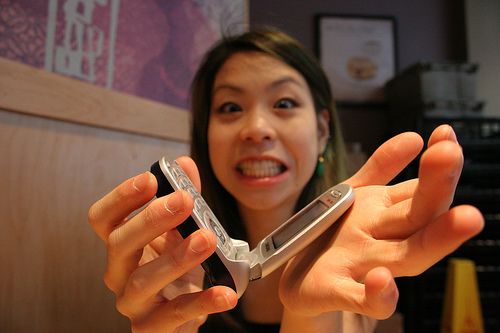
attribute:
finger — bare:
[84, 173, 156, 244]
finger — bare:
[339, 145, 489, 302]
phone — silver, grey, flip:
[149, 152, 353, 304]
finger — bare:
[384, 105, 484, 276]